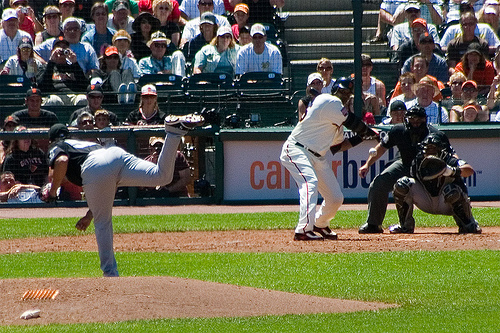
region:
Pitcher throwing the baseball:
[38, 112, 204, 275]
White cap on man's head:
[246, 20, 263, 37]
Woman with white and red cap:
[136, 77, 157, 92]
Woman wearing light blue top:
[190, 42, 236, 74]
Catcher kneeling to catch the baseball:
[390, 130, 485, 236]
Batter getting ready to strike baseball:
[277, 75, 379, 237]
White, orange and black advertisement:
[228, 138, 494, 193]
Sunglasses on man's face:
[150, 38, 166, 48]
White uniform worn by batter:
[275, 90, 353, 231]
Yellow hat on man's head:
[109, 28, 134, 43]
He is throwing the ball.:
[25, 113, 227, 263]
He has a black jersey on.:
[24, 98, 121, 190]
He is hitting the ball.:
[280, 81, 397, 244]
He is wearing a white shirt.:
[262, 89, 369, 242]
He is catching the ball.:
[383, 131, 485, 245]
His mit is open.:
[387, 148, 489, 223]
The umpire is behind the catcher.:
[376, 105, 432, 176]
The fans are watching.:
[12, 15, 473, 125]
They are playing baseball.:
[15, 1, 486, 315]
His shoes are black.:
[291, 213, 351, 245]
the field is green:
[385, 266, 460, 302]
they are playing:
[405, 260, 470, 325]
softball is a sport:
[400, 250, 470, 310]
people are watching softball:
[405, 270, 455, 295]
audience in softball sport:
[405, 270, 465, 305]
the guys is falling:
[405, 265, 450, 305]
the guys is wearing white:
[415, 255, 470, 310]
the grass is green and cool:
[415, 280, 460, 305]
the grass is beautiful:
[415, 275, 460, 305]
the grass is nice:
[416, 275, 461, 307]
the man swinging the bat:
[271, 55, 398, 243]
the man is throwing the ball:
[36, 110, 241, 277]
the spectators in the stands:
[11, 5, 278, 95]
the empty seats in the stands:
[146, 65, 293, 120]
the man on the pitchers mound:
[30, 100, 221, 267]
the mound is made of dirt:
[15, 275, 345, 322]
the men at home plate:
[295, 50, 485, 250]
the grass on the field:
[306, 250, 491, 295]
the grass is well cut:
[310, 255, 490, 301]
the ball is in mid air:
[357, 142, 384, 162]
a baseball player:
[8, 105, 225, 265]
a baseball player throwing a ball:
[20, 65, 224, 287]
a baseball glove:
[404, 138, 455, 188]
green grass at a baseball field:
[272, 230, 483, 330]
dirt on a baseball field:
[3, 269, 380, 319]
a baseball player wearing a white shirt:
[278, 67, 388, 184]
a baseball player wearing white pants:
[245, 71, 384, 240]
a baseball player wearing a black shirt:
[358, 99, 442, 181]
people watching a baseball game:
[1, 23, 305, 92]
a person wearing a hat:
[118, 77, 188, 140]